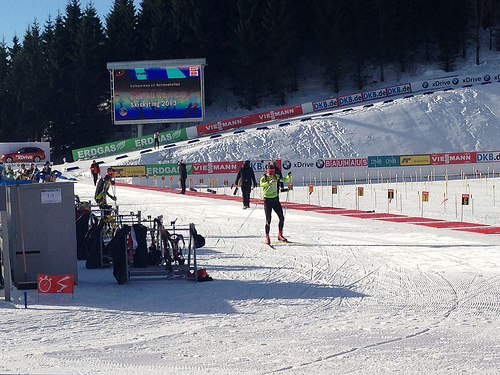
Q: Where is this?
A: This is at the path.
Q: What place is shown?
A: It is a path.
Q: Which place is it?
A: It is a path.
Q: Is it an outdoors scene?
A: Yes, it is outdoors.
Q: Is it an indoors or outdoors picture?
A: It is outdoors.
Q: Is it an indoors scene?
A: No, it is outdoors.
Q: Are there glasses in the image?
A: No, there are no glasses.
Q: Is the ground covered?
A: Yes, the ground is covered.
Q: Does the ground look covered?
A: Yes, the ground is covered.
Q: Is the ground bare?
A: No, the ground is covered.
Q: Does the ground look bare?
A: No, the ground is covered.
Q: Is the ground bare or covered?
A: The ground is covered.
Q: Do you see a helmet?
A: No, there are no helmets.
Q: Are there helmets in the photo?
A: No, there are no helmets.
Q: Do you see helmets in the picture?
A: No, there are no helmets.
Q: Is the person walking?
A: Yes, the person is walking.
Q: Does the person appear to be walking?
A: Yes, the person is walking.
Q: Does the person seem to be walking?
A: Yes, the person is walking.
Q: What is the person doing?
A: The person is walking.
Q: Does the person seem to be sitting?
A: No, the person is walking.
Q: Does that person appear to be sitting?
A: No, the person is walking.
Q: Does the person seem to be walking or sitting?
A: The person is walking.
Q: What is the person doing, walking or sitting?
A: The person is walking.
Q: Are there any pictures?
A: No, there are no pictures.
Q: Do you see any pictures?
A: No, there are no pictures.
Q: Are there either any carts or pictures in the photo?
A: No, there are no pictures or carts.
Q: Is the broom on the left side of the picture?
A: Yes, the broom is on the left of the image.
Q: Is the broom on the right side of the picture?
A: No, the broom is on the left of the image.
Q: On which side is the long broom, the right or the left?
A: The broom is on the left of the image.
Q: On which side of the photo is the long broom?
A: The broom is on the left of the image.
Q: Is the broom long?
A: Yes, the broom is long.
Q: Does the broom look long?
A: Yes, the broom is long.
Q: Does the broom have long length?
A: Yes, the broom is long.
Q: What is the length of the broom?
A: The broom is long.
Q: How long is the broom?
A: The broom is long.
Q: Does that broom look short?
A: No, the broom is long.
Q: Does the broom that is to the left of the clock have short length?
A: No, the broom is long.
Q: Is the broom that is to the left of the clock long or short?
A: The broom is long.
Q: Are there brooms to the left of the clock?
A: Yes, there is a broom to the left of the clock.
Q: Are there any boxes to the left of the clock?
A: No, there is a broom to the left of the clock.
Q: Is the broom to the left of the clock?
A: Yes, the broom is to the left of the clock.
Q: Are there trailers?
A: No, there are no trailers.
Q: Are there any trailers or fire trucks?
A: No, there are no trailers or fire trucks.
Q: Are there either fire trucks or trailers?
A: No, there are no trailers or fire trucks.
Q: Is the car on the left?
A: Yes, the car is on the left of the image.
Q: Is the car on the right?
A: No, the car is on the left of the image.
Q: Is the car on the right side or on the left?
A: The car is on the left of the image.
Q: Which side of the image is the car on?
A: The car is on the left of the image.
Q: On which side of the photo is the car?
A: The car is on the left of the image.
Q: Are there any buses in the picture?
A: No, there are no buses.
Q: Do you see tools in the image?
A: No, there are no tools.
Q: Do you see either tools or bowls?
A: No, there are no tools or bowls.